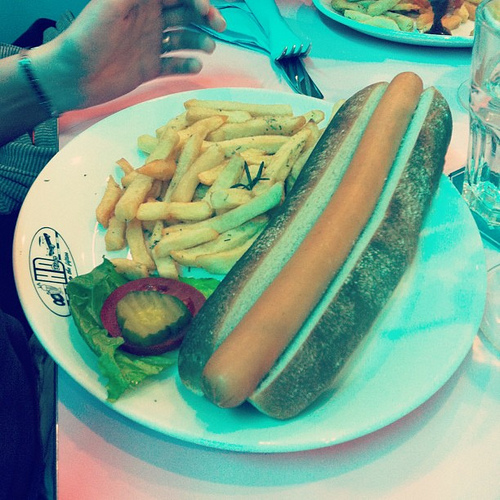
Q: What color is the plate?
A: White.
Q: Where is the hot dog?
A: In bun.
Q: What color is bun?
A: Brown.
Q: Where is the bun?
A: On plate.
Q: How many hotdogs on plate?
A: One.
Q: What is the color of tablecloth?
A: White.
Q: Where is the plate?
A: On table.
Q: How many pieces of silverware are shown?
A: Two.